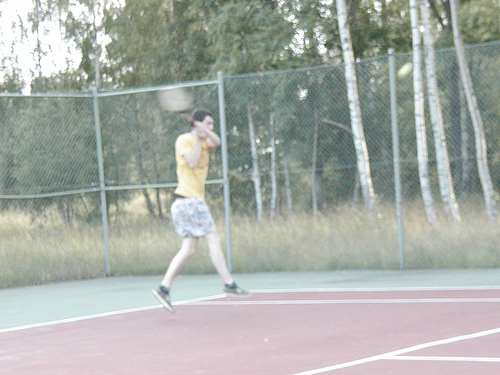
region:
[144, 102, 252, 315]
man playing a tennis match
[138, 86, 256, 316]
man standing on tennis court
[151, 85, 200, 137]
man swinging tennis racket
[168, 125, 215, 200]
man wearing yellow shirt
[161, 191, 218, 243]
man wearing pair of shorts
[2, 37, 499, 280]
fence separating court and grass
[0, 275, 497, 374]
court is a red clay color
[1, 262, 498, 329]
out of bounds area is green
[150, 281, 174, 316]
mans right foot off the ground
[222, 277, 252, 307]
mans left foot off the ground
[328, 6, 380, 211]
a trunk of a tree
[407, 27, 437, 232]
a trunk of a tree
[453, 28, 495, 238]
a trunk of a tree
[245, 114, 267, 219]
a trunk of a tree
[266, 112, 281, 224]
a trunk of a tree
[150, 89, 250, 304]
a man playing tennis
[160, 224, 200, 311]
the leg of a man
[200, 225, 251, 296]
the leg of a man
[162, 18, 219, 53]
the leaves of a tree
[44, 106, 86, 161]
the green of the leaves of a tree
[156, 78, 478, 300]
playing tennis in the woods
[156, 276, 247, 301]
black ankle socks with black sneakers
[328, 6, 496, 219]
young white birch trees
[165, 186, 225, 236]
baggy print shorts are falling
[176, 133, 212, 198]
a yellow t-shirt over black underwear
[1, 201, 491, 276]
tell grass in the trees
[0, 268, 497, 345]
a green walkway around a clay red tennis court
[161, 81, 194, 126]
a blurred tennis racwuet is being moved to catch the tennis ball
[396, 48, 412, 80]
a tennis ball in motion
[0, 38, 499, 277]
a tall chain link fence around the court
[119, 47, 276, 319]
this is a man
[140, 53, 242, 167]
this is a tennis racket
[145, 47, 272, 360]
man swinging a tennis racket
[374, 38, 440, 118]
this is a tennis ball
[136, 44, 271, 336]
man is playing tennis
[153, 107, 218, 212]
man wearing a yellow shirt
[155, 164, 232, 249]
man is wearing shorts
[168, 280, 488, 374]
lines on the tennis court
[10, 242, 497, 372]
the tennis court is red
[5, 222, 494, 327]
green trim around court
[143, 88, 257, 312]
man standing in midair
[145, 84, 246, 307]
man playing tennis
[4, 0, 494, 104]
line of tree behind tennis court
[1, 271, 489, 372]
tennis court is green and red, with white lines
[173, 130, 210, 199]
man wearing yellow t-shirt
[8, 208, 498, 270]
tall grass around tennis court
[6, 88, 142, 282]
meshed fence around tennis court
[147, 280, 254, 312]
man wearing dark sport shoes and short socks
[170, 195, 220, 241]
man wearing short pants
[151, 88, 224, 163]
man holding tennis racket